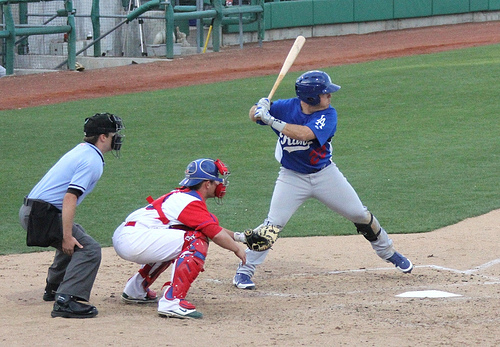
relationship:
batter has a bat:
[233, 67, 412, 288] [252, 34, 305, 116]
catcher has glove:
[108, 155, 246, 318] [242, 220, 282, 254]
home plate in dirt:
[394, 285, 459, 302] [2, 204, 496, 347]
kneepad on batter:
[173, 231, 209, 291] [233, 67, 412, 288]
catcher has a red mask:
[108, 155, 246, 318] [211, 157, 231, 201]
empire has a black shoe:
[18, 112, 124, 318] [52, 294, 99, 318]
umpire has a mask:
[18, 112, 124, 323] [112, 112, 126, 153]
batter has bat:
[233, 67, 412, 288] [252, 34, 305, 116]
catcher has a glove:
[108, 155, 246, 318] [242, 220, 282, 254]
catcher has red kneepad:
[108, 155, 246, 318] [173, 231, 209, 291]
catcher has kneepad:
[108, 155, 246, 318] [173, 231, 209, 291]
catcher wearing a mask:
[108, 155, 246, 318] [211, 157, 231, 201]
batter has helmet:
[233, 67, 412, 288] [295, 70, 341, 104]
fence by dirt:
[1, 3, 263, 69] [2, 204, 496, 347]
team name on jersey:
[275, 131, 315, 154] [258, 97, 338, 175]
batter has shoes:
[233, 67, 412, 288] [228, 252, 413, 291]